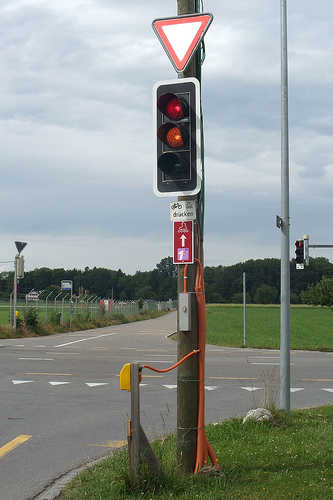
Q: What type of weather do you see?
A: It is cloudy.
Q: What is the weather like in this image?
A: It is cloudy.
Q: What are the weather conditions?
A: It is cloudy.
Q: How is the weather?
A: It is cloudy.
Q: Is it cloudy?
A: Yes, it is cloudy.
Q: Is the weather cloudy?
A: Yes, it is cloudy.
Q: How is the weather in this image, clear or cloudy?
A: It is cloudy.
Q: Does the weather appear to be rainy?
A: No, it is cloudy.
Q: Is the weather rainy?
A: No, it is cloudy.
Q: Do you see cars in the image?
A: No, there are no cars.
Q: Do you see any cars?
A: No, there are no cars.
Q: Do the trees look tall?
A: Yes, the trees are tall.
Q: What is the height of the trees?
A: The trees are tall.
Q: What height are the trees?
A: The trees are tall.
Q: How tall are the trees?
A: The trees are tall.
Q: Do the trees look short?
A: No, the trees are tall.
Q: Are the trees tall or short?
A: The trees are tall.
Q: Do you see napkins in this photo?
A: No, there are no napkins.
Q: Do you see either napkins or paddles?
A: No, there are no napkins or paddles.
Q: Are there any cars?
A: No, there are no cars.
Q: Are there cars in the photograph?
A: No, there are no cars.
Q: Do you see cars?
A: No, there are no cars.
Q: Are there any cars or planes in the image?
A: No, there are no cars or planes.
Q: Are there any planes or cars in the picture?
A: No, there are no cars or planes.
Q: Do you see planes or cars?
A: No, there are no cars or planes.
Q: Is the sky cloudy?
A: Yes, the sky is cloudy.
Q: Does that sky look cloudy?
A: Yes, the sky is cloudy.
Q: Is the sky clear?
A: No, the sky is cloudy.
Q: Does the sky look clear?
A: No, the sky is cloudy.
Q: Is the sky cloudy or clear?
A: The sky is cloudy.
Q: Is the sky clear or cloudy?
A: The sky is cloudy.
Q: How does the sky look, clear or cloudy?
A: The sky is cloudy.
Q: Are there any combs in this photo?
A: No, there are no combs.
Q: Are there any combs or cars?
A: No, there are no combs or cars.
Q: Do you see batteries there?
A: No, there are no batteries.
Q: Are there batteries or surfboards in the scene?
A: No, there are no batteries or surfboards.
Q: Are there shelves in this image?
A: No, there are no shelves.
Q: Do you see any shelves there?
A: No, there are no shelves.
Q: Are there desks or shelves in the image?
A: No, there are no shelves or desks.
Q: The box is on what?
A: The box is on the pole.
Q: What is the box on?
A: The box is on the pole.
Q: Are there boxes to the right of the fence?
A: Yes, there is a box to the right of the fence.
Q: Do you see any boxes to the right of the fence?
A: Yes, there is a box to the right of the fence.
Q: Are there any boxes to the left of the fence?
A: No, the box is to the right of the fence.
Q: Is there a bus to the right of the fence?
A: No, there is a box to the right of the fence.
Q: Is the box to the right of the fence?
A: Yes, the box is to the right of the fence.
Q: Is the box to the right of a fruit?
A: No, the box is to the right of the fence.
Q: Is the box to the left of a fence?
A: No, the box is to the right of a fence.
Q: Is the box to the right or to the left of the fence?
A: The box is to the right of the fence.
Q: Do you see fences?
A: Yes, there is a fence.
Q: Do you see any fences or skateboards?
A: Yes, there is a fence.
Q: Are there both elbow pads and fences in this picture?
A: No, there is a fence but no elbow pads.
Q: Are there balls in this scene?
A: No, there are no balls.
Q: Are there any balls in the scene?
A: No, there are no balls.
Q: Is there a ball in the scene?
A: No, there are no balls.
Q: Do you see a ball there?
A: No, there are no balls.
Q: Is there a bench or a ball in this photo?
A: No, there are no balls or benches.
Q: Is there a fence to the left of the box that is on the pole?
A: Yes, there is a fence to the left of the box.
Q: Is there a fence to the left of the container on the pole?
A: Yes, there is a fence to the left of the box.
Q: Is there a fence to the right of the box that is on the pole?
A: No, the fence is to the left of the box.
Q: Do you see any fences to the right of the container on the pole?
A: No, the fence is to the left of the box.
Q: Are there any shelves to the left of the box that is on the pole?
A: No, there is a fence to the left of the box.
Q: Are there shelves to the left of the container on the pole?
A: No, there is a fence to the left of the box.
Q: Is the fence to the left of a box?
A: Yes, the fence is to the left of a box.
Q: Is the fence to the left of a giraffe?
A: No, the fence is to the left of a box.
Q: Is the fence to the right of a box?
A: No, the fence is to the left of a box.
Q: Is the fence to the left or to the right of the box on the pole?
A: The fence is to the left of the box.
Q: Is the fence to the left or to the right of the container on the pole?
A: The fence is to the left of the box.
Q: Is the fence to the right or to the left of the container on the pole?
A: The fence is to the left of the box.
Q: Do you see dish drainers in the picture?
A: No, there are no dish drainers.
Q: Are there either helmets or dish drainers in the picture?
A: No, there are no dish drainers or helmets.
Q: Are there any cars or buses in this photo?
A: No, there are no cars or buses.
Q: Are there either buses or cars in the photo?
A: No, there are no cars or buses.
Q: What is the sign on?
A: The sign is on the pole.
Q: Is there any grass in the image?
A: Yes, there is grass.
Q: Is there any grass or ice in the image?
A: Yes, there is grass.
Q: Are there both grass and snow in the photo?
A: No, there is grass but no snow.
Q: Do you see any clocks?
A: No, there are no clocks.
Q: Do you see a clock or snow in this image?
A: No, there are no clocks or snow.